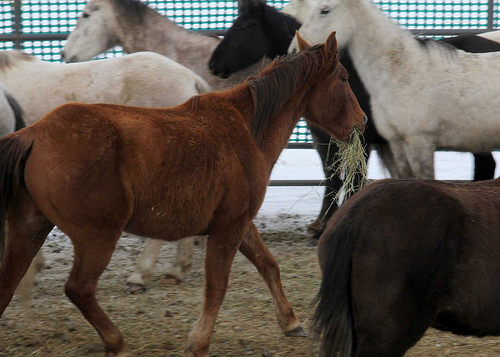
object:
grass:
[284, 127, 373, 221]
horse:
[0, 30, 368, 357]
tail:
[0, 133, 26, 226]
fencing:
[0, 0, 499, 147]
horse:
[59, 0, 274, 92]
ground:
[0, 147, 499, 356]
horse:
[201, 0, 500, 245]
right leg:
[182, 188, 264, 356]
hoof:
[284, 327, 309, 338]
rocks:
[164, 308, 174, 317]